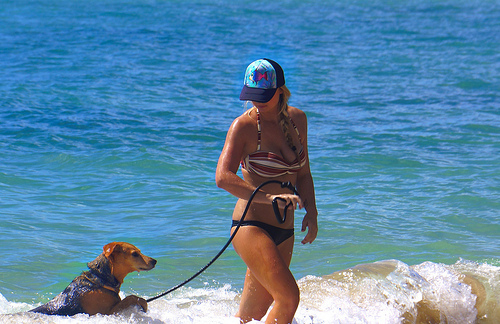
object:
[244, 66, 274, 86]
fish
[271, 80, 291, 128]
hair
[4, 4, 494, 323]
body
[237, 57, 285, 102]
cap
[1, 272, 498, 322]
beach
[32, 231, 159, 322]
dog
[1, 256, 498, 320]
waves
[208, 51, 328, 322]
woman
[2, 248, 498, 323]
surf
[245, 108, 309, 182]
top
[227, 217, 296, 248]
bottom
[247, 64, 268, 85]
image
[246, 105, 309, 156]
straps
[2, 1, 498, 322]
water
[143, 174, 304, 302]
leash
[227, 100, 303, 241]
bikini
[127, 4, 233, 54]
ocean